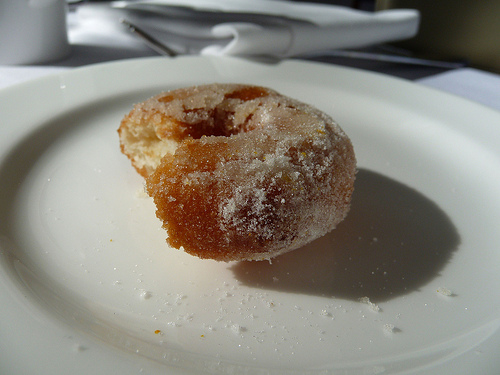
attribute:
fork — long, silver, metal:
[109, 17, 469, 83]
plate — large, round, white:
[0, 55, 500, 369]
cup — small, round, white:
[48, 62, 486, 372]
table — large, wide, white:
[282, 29, 462, 93]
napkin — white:
[61, 1, 421, 59]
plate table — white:
[114, 75, 496, 357]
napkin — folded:
[179, 13, 390, 63]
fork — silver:
[107, 19, 325, 64]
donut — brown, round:
[119, 55, 321, 221]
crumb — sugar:
[117, 105, 328, 332]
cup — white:
[3, 0, 65, 60]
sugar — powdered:
[224, 152, 345, 229]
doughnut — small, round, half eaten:
[116, 82, 358, 260]